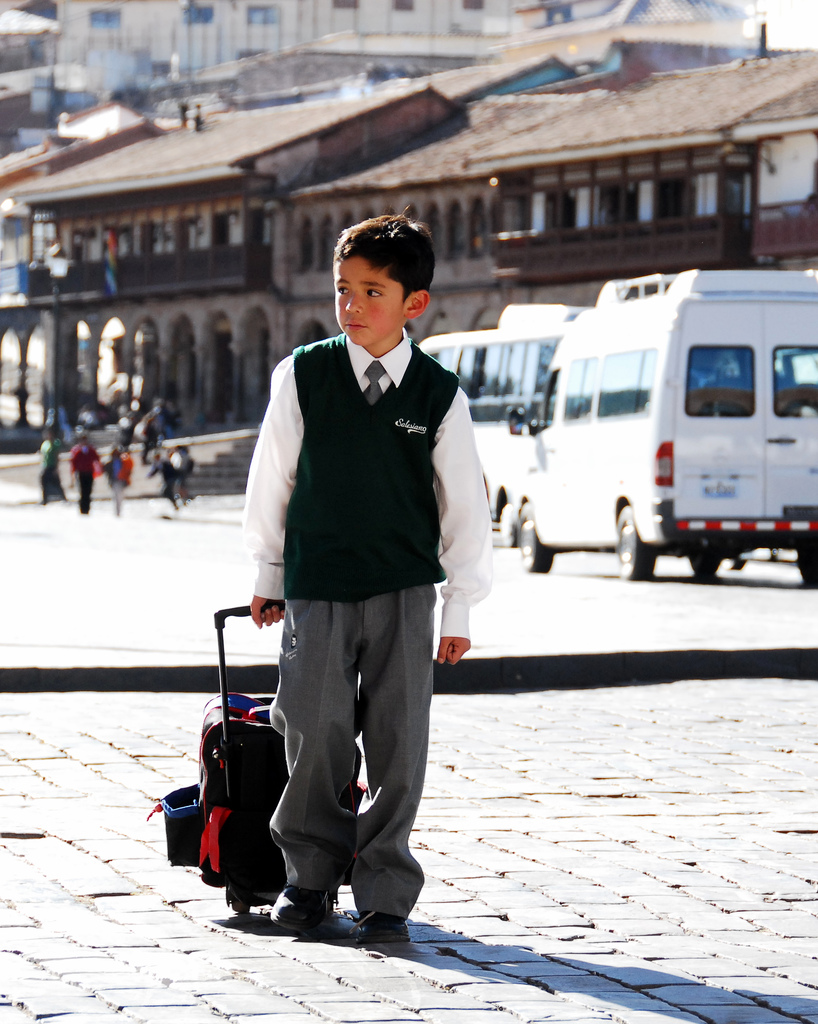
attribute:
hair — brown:
[334, 208, 438, 292]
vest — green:
[286, 333, 460, 602]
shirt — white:
[246, 325, 494, 631]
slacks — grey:
[272, 592, 437, 922]